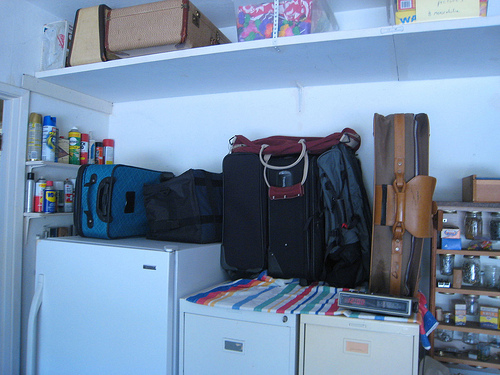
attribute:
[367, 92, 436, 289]
suitcase — brown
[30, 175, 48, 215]
can — white, red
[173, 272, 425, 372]
cabinets — file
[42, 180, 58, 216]
wd-40 — can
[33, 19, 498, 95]
shelf — above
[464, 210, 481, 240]
trinket — small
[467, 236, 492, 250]
trinket — small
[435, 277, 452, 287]
trinket — small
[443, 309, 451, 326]
trinket — small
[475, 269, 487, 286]
trinket — small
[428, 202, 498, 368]
shelf — small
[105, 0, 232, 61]
suitcase — brown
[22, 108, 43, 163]
spraypaint — gold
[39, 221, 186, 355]
refrigerator — compact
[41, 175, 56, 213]
can — w-d40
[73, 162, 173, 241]
tote bag — black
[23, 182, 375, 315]
can — green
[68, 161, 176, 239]
suitcase — black, blue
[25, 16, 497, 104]
shelf — white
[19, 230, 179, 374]
refrigerator — white, small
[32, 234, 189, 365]
fridge — small, white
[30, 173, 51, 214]
can — red, white, spray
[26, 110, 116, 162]
cans — spray paint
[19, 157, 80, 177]
shelf — full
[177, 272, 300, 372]
cabinet — file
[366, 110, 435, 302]
bag — luggage